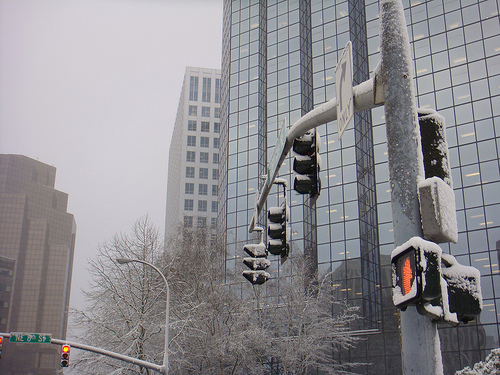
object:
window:
[189, 76, 198, 101]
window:
[202, 77, 211, 102]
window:
[215, 78, 220, 103]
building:
[216, 1, 500, 373]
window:
[240, 18, 250, 36]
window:
[277, 26, 288, 43]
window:
[250, 28, 259, 43]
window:
[267, 4, 278, 20]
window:
[289, 10, 300, 26]